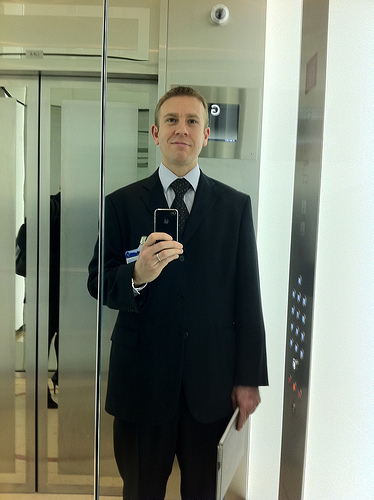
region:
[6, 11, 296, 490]
man standing in elevator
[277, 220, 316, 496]
panel on the wall with buttons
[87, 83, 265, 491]
man is taking a picture of himself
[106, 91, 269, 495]
man is wearing a black suit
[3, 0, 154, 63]
mouding above the door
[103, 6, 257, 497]
chrome elevator doors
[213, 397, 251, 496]
man holding a thin laptop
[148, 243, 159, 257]
man is wearing a ring on his finger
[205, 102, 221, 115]
G for ground floor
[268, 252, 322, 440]
Control panels in the elevator.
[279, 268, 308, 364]
Blue buttons on the panel.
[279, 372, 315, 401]
Red buttons on the panel.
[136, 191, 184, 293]
Hand holding a cell phone.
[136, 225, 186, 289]
Ring being worn on the finger.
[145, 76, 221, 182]
Man smiling for his selfie.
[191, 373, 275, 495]
Hand holding a notebook.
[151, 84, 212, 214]
Man wearing a tie.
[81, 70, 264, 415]
Man wearing a business suit.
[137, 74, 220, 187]
The man has a small smile on his face.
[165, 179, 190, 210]
the tie is long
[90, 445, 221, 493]
pants on the man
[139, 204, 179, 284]
phone in man's hand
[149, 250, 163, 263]
ring on the finger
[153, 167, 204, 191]
collar of the shirt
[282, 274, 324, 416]
buttons of the elevator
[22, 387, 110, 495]
door of the elevator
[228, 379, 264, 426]
hand of the man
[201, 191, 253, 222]
shoulder of the man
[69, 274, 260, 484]
the man is standing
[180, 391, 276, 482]
the man is holding a board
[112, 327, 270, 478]
the pants are black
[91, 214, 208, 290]
the man is holding a phone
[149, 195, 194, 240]
the phone is black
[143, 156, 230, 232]
the shirt under is white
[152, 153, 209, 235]
this is a neck tie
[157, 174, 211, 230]
the neck tie is black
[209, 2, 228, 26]
camera is attached to wall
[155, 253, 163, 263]
ring is worn on finger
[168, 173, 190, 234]
tie is worn by human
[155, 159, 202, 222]
shirt is worn by human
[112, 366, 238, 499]
pants are worn by human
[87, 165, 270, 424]
suit jacket is worn by human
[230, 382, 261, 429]
hand belongs to human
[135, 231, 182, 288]
hand belongs to human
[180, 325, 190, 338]
button is attached to jacket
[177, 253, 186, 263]
button is attached to jacket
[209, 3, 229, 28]
security camera sits on wall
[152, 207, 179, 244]
phone is held by hand of human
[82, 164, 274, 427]
jacket is worn by human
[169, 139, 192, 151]
mouth belongs to human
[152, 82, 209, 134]
hair belongs to human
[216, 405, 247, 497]
the pad of paper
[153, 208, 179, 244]
the phone is black and silver